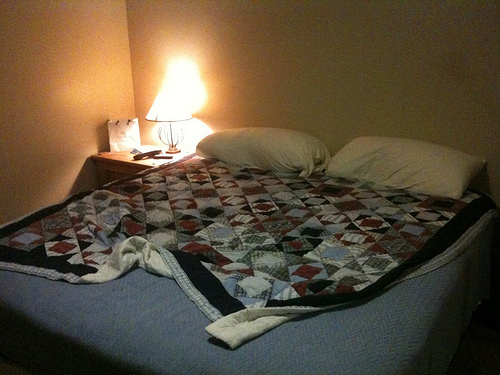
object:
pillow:
[195, 126, 331, 177]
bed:
[1, 128, 498, 374]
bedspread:
[0, 153, 498, 349]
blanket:
[0, 148, 498, 347]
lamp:
[145, 87, 195, 154]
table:
[90, 145, 194, 187]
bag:
[107, 117, 141, 152]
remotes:
[154, 154, 173, 158]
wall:
[0, 0, 135, 222]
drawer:
[99, 159, 144, 174]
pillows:
[323, 136, 486, 199]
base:
[165, 148, 180, 154]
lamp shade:
[144, 91, 193, 122]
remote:
[133, 149, 163, 160]